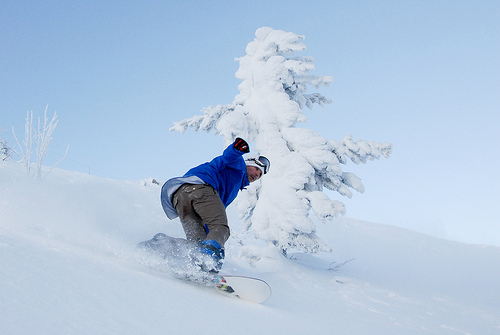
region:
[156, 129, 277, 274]
man on a snow board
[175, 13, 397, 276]
tree behind a man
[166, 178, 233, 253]
man's grey colored pants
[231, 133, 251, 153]
black and red glove on right hand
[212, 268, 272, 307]
nose of white snowboard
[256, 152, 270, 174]
goggles on man's head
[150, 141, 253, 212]
man's blue snow jacket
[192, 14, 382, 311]
the tree is snow covered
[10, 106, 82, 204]
the tree is snow covered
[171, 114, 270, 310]
the person is snow boarding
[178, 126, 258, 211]
the jacket is blue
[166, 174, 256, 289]
the pants are tan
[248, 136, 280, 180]
the hat is white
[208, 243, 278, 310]
the board is white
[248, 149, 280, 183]
the glasses are white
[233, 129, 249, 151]
the glove is black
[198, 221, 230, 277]
the boot is blue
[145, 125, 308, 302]
this is a person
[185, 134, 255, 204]
the person is in a blue jacket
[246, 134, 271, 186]
this is a helmet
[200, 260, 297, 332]
this is a surfboard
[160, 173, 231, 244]
the pants are grey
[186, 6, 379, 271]
a tree covered with snow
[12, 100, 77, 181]
a tree without leaves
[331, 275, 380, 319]
snow on the ground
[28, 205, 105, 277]
snow on the ground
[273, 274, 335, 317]
snow on the ground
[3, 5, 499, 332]
Exterior view, daytime, winter.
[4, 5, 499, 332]
Outdoor winter landscape, showing winter sports enthusiast.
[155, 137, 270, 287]
Snowboarder, hurdling downhill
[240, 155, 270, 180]
Head with knit cap and goggles.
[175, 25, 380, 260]
Tree crusted over with snow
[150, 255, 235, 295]
snowboard kicking up snow, as it travels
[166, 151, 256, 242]
Blue jacket and shirttail over tan pants.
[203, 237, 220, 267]
Blue boot, semi-covered in snow.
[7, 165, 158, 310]
pristine mountain slope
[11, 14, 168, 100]
Beautiful, ice-blue sky.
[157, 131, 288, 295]
This is a person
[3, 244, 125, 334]
Section of an ocean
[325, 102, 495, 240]
Section of an ocean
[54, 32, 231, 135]
Section of an ocean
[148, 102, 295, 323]
the man is snowboarding